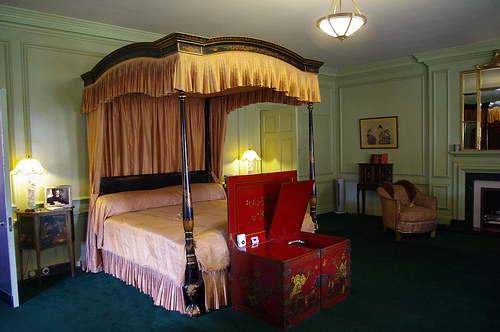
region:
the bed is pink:
[106, 176, 183, 274]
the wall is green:
[26, 73, 74, 146]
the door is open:
[253, 100, 318, 190]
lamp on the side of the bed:
[10, 139, 116, 279]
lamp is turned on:
[8, 154, 63, 194]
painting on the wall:
[348, 112, 454, 169]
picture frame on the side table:
[48, 186, 81, 233]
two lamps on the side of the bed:
[12, 131, 322, 218]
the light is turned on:
[295, 6, 400, 63]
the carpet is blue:
[36, 275, 135, 327]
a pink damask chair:
[371, 181, 449, 242]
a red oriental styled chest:
[234, 171, 351, 319]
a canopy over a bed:
[76, 31, 315, 96]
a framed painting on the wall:
[356, 108, 409, 152]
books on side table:
[365, 149, 391, 161]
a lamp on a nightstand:
[11, 154, 46, 214]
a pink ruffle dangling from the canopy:
[183, 54, 288, 86]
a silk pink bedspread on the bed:
[118, 201, 178, 259]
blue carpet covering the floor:
[77, 292, 133, 320]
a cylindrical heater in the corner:
[331, 172, 351, 219]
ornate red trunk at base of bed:
[223, 154, 353, 328]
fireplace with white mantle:
[449, 153, 496, 240]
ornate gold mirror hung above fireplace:
[454, 41, 499, 154]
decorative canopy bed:
[85, 23, 327, 318]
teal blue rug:
[45, 283, 110, 323]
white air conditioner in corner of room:
[330, 167, 357, 219]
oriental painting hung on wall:
[342, 107, 414, 154]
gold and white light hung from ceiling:
[305, 7, 385, 62]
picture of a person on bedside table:
[46, 178, 80, 211]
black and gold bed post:
[168, 86, 203, 316]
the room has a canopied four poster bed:
[0, 3, 496, 326]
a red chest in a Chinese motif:
[220, 166, 351, 323]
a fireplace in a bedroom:
[165, 2, 497, 249]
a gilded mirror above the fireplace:
[445, 46, 497, 236]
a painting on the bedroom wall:
[335, 67, 428, 182]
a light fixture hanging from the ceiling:
[302, 5, 375, 61]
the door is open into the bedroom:
[222, 70, 342, 265]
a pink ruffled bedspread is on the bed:
[87, 176, 322, 313]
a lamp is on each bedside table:
[5, 145, 265, 315]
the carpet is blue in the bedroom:
[5, 203, 497, 326]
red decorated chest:
[223, 170, 355, 327]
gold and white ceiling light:
[315, 1, 368, 43]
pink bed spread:
[86, 179, 315, 314]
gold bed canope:
[80, 31, 325, 310]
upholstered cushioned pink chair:
[379, 180, 446, 245]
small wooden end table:
[17, 206, 80, 286]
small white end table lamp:
[12, 157, 48, 212]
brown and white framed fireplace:
[460, 168, 498, 238]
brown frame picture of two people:
[356, 114, 400, 149]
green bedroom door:
[260, 107, 303, 174]